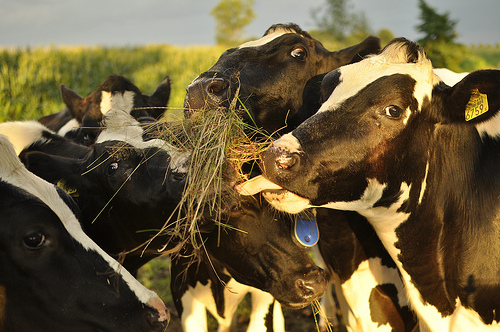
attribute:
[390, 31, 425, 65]
hair — black, white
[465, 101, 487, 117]
number — black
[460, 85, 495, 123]
tag — yellow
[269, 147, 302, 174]
nose — pink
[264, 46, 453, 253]
cow — black, white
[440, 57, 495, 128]
tag — yellow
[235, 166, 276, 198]
tongue — pink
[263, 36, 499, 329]
cow — black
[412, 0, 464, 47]
tree — green, tall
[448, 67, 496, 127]
ear — yellow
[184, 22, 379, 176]
cow — black, white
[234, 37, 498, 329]
cow — black, white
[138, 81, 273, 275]
hay — yellow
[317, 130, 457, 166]
fur — black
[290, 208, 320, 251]
tag — blue